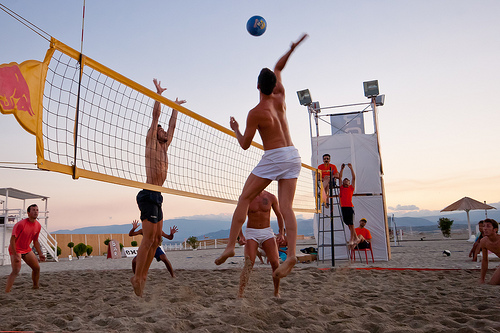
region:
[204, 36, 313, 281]
a man wearing white shorts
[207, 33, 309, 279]
a man jumping in mid air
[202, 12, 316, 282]
a man preparing to hit a ball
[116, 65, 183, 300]
a man in black shorts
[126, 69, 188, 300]
a man playing volleyball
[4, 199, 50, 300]
a volleyball player standing in sand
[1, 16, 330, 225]
a yellow volleyball net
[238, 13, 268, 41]
a blue and yellow volleyball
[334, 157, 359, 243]
a man wearing red and black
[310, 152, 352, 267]
a referee sitting on a high chair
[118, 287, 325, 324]
brown sand on the beach enclosure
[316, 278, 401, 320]
depressions in the sand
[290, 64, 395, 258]
tall white life guard stand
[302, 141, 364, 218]
life guards sitting on ladder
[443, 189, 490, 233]
large brown beach umbrella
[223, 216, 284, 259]
hunk in white shorts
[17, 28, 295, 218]
large yellow volley ball net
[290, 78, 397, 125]
large silver flood lights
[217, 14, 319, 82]
man spiking volley ball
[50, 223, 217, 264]
yellow and white barrier on side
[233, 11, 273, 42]
volley ball in flight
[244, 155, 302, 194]
lines in man's shorts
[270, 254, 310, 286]
sand under man's feet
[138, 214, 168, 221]
white logo on black shorts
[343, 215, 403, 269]
man sitting in chair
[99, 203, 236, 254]
long blue mountain range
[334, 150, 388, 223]
man taking picture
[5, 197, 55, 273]
man crouching in the sand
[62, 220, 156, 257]
large yellow and white fence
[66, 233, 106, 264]
large pots of green plants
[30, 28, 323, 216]
Yellow volleyball net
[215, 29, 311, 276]
Man in white shorts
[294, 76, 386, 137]
Beach lights on top of concret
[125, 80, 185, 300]
Man with black shorts jumping in air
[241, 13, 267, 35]
Volleyball being hit by players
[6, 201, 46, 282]
Man wearing orange tee shirt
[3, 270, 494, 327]
Sand with footprints in it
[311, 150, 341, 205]
Man sitting on chair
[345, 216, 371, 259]
Man sitting with orange shirt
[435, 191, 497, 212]
Small hill in the distance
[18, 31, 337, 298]
men playing volleyball on the beach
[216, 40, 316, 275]
man getting ready to hit the ball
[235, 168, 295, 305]
man wearing white shorts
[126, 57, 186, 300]
man wearing black shorts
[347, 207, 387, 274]
man sitting in a red chair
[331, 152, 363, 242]
man wearing a orange shirt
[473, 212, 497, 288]
man kneeling in the sand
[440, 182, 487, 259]
beige umbrella in the sand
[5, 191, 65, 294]
man wearing a red shirt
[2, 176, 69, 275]
white life guard booth